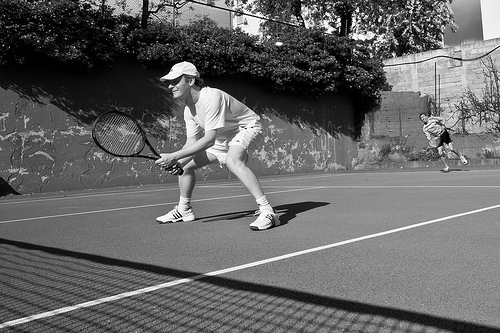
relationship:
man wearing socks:
[156, 60, 282, 230] [173, 199, 279, 213]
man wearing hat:
[156, 60, 282, 230] [142, 52, 209, 87]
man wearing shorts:
[156, 60, 282, 230] [208, 117, 262, 157]